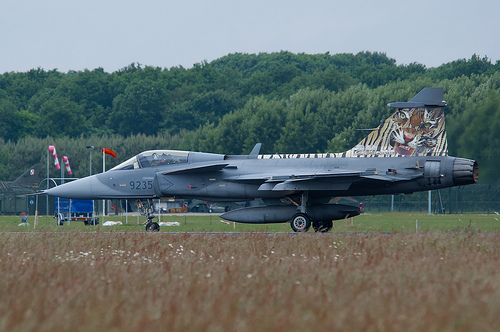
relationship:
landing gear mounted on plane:
[137, 198, 162, 232] [38, 87, 480, 231]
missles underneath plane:
[223, 199, 383, 239] [39, 82, 479, 201]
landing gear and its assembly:
[139, 205, 164, 238] [122, 199, 185, 303]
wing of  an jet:
[220, 164, 436, 191] [38, 86, 482, 234]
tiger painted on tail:
[384, 107, 441, 158] [350, 86, 480, 185]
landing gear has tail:
[137, 198, 162, 232] [348, 86, 450, 158]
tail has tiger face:
[348, 86, 450, 158] [384, 106, 446, 155]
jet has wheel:
[38, 86, 482, 234] [141, 222, 163, 234]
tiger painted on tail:
[386, 106, 437, 160] [348, 86, 450, 158]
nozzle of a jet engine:
[451, 157, 478, 184] [375, 147, 481, 194]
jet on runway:
[34, 94, 479, 231] [4, 212, 488, 239]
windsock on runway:
[102, 146, 120, 158] [11, 221, 499, 230]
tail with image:
[348, 86, 450, 158] [388, 109, 440, 152]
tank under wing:
[224, 204, 363, 227] [227, 167, 376, 195]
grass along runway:
[0, 213, 499, 331] [1, 225, 499, 241]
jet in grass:
[34, 94, 479, 231] [5, 211, 497, 314]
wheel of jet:
[288, 213, 308, 234] [34, 94, 479, 231]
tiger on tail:
[386, 106, 437, 160] [350, 86, 453, 160]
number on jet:
[127, 177, 157, 191] [34, 94, 479, 231]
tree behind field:
[206, 54, 392, 103] [4, 205, 494, 325]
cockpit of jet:
[106, 148, 186, 171] [34, 94, 479, 231]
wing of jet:
[243, 162, 437, 191] [34, 94, 479, 231]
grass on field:
[18, 231, 481, 324] [7, 204, 484, 305]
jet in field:
[34, 94, 479, 231] [14, 212, 457, 326]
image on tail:
[371, 111, 447, 159] [354, 88, 449, 154]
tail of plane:
[354, 88, 449, 154] [38, 87, 480, 231]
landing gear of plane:
[294, 209, 344, 241] [38, 87, 480, 231]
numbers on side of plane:
[127, 178, 159, 194] [38, 87, 480, 231]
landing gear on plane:
[140, 216, 168, 237] [38, 87, 480, 231]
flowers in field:
[65, 245, 345, 265] [13, 208, 483, 314]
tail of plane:
[348, 86, 450, 158] [38, 87, 480, 231]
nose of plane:
[42, 171, 103, 202] [42, 100, 476, 240]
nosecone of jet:
[41, 177, 92, 205] [43, 81, 482, 232]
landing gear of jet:
[289, 190, 335, 235] [44, 101, 483, 218]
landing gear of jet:
[137, 198, 162, 232] [34, 94, 479, 231]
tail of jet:
[348, 86, 450, 158] [43, 81, 482, 232]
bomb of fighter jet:
[226, 201, 362, 229] [43, 79, 457, 229]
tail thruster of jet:
[454, 154, 484, 187] [38, 86, 482, 234]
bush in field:
[14, 229, 479, 329] [2, 204, 484, 294]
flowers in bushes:
[55, 247, 336, 270] [11, 228, 482, 325]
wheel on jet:
[288, 213, 311, 234] [17, 63, 480, 233]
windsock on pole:
[102, 147, 116, 158] [100, 153, 108, 221]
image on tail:
[351, 106, 446, 157] [353, 82, 450, 152]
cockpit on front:
[106, 150, 187, 171] [20, 140, 190, 231]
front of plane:
[20, 140, 190, 231] [19, 72, 477, 233]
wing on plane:
[220, 164, 436, 191] [38, 87, 480, 231]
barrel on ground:
[180, 203, 190, 214] [10, 201, 480, 322]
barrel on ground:
[173, 205, 178, 213] [10, 201, 480, 322]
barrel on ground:
[167, 204, 173, 211] [10, 201, 480, 322]